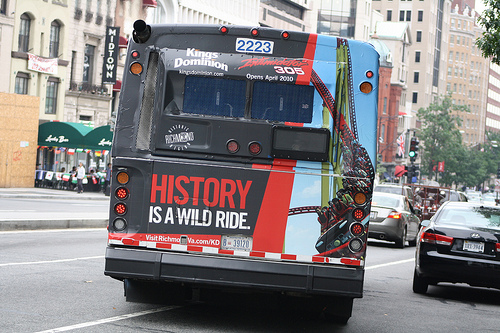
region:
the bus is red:
[266, 204, 278, 231]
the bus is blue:
[320, 48, 330, 67]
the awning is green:
[60, 124, 77, 136]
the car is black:
[431, 257, 452, 273]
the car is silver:
[377, 203, 387, 225]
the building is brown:
[381, 76, 389, 94]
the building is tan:
[453, 56, 466, 76]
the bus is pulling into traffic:
[352, 205, 397, 250]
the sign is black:
[106, 35, 116, 65]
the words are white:
[170, 208, 212, 225]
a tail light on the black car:
[419, 225, 452, 249]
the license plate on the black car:
[463, 235, 484, 254]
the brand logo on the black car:
[467, 223, 482, 242]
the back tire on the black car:
[414, 266, 428, 296]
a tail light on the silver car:
[388, 206, 406, 223]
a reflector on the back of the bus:
[113, 164, 134, 184]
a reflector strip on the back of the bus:
[118, 243, 298, 259]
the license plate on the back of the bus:
[219, 232, 254, 254]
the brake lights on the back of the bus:
[350, 207, 362, 238]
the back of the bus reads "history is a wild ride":
[145, 165, 252, 231]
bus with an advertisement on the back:
[100, 12, 392, 315]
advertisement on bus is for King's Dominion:
[163, 35, 235, 83]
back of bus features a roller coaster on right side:
[295, 18, 371, 270]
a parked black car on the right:
[412, 182, 497, 302]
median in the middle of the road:
[1, 205, 106, 226]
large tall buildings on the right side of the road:
[12, 0, 483, 176]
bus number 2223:
[230, 27, 280, 60]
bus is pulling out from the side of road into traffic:
[35, 0, 466, 325]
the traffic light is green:
[405, 130, 421, 190]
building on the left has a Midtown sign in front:
[79, 22, 122, 92]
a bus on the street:
[106, 25, 371, 302]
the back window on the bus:
[170, 70, 315, 130]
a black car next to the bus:
[411, 195, 492, 275]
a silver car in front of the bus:
[370, 185, 410, 237]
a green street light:
[401, 130, 421, 160]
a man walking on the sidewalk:
[75, 156, 85, 191]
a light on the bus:
[361, 81, 372, 93]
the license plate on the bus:
[215, 233, 251, 248]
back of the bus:
[76, 27, 430, 326]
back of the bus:
[120, 29, 393, 303]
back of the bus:
[67, 30, 373, 305]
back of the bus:
[110, 49, 355, 271]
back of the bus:
[95, 46, 378, 311]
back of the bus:
[130, 68, 344, 295]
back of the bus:
[113, 51, 358, 298]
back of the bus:
[108, 48, 368, 247]